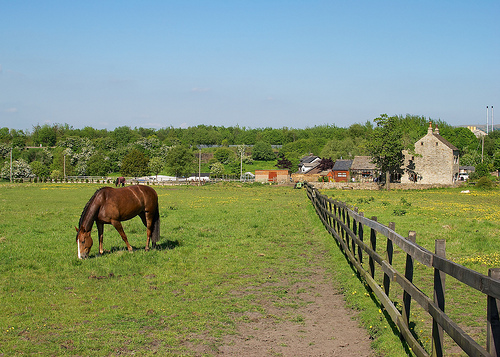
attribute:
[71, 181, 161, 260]
horse — brown 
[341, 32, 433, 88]
cloud — white 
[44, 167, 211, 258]
horse — brown 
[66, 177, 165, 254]
horse — brown, white, grazing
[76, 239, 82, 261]
stripe — white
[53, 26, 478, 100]
sky — clear, blue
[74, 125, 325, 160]
trees — green 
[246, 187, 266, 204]
flowers — yellow 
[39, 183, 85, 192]
wildflowers — yellow 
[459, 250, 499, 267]
wildflowers — yellow 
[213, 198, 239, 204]
wildflowers — yellow 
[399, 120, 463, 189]
barn — white 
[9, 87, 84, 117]
clouds — white 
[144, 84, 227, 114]
clouds — white 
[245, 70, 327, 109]
clouds — white 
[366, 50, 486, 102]
clouds — white 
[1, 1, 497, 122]
sky — blue 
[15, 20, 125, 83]
clouds — white 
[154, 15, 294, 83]
clouds — white 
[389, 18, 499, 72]
clouds — white 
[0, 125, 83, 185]
trees — green 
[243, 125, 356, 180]
trees — green 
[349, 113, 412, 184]
trees — green 